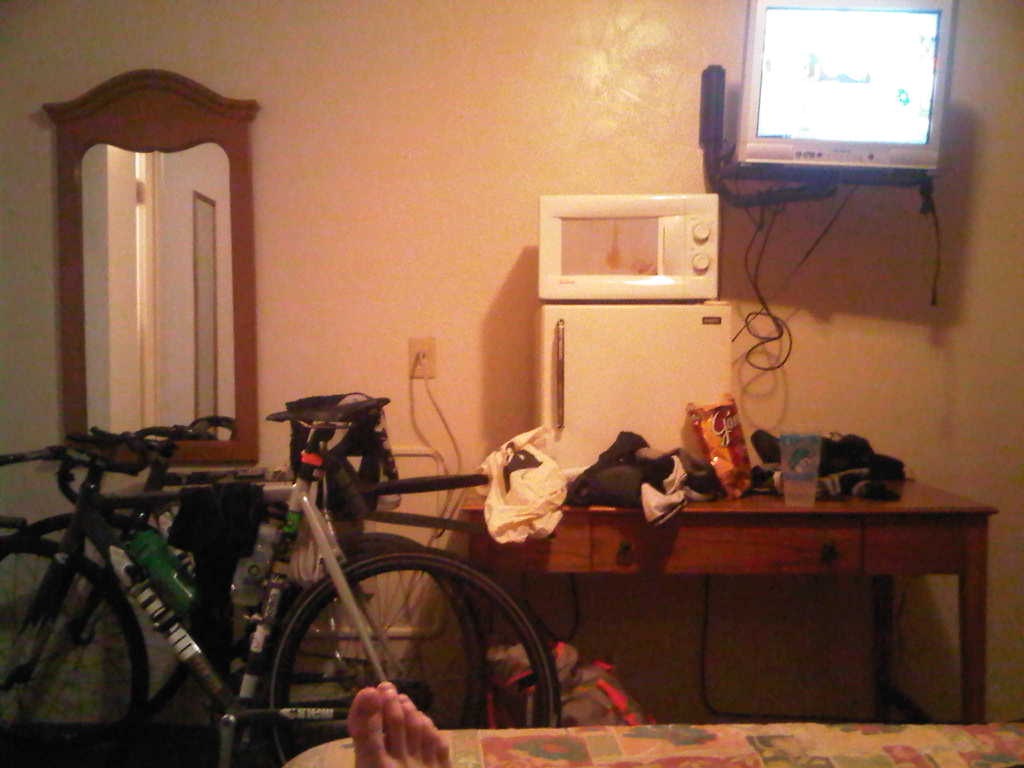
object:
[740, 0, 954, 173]
television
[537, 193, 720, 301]
microwave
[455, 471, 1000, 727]
table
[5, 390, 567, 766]
bike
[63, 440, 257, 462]
wood frame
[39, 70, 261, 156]
wood frame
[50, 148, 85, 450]
wood frame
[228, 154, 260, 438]
wood frame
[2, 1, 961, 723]
wall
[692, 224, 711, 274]
dials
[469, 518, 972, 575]
drawer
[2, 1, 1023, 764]
building